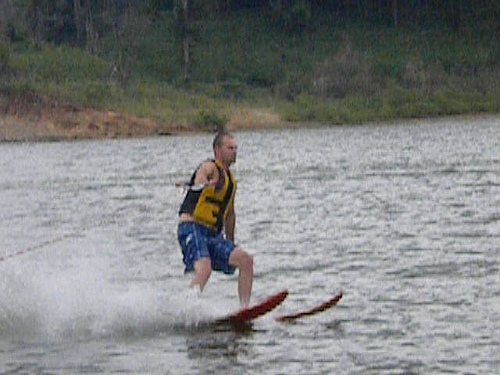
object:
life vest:
[177, 157, 238, 233]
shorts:
[175, 221, 238, 276]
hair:
[212, 131, 233, 156]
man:
[177, 131, 253, 309]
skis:
[213, 289, 289, 323]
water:
[0, 114, 499, 374]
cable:
[1, 181, 210, 262]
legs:
[212, 236, 252, 306]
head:
[212, 131, 238, 163]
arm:
[195, 162, 216, 177]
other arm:
[224, 182, 236, 241]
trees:
[0, 0, 499, 141]